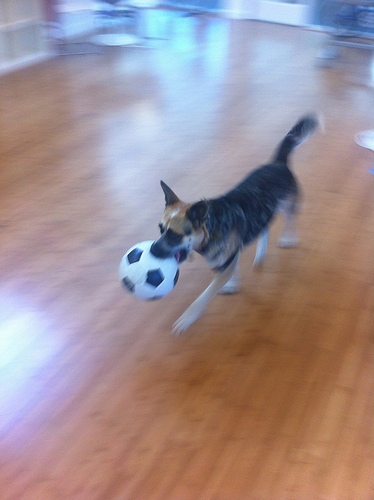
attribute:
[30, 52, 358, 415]
floor — hardwood, wood, shiny, wooden, polished, laminated, bare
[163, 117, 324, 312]
dog — white, black, brown, walking, running, excited, hyper, playing, happy, tan, young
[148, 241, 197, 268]
mouth — open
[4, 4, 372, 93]
background — blurry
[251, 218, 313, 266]
legs — white, light colored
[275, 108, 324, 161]
tail — wagging, white, black, bushy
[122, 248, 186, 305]
ball — white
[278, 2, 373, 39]
furniture — blurred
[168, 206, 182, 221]
spot — white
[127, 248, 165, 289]
pentagons — black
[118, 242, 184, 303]
soccer ball — white, black